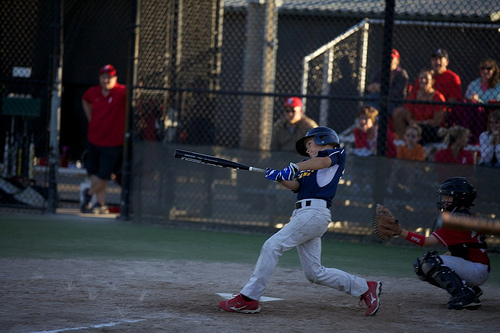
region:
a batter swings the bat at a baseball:
[173, 105, 387, 320]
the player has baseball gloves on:
[263, 160, 298, 192]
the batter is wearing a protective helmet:
[292, 123, 344, 159]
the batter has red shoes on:
[221, 277, 386, 324]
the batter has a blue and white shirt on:
[235, 148, 369, 208]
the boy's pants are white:
[246, 198, 369, 301]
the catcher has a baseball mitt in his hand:
[368, 178, 494, 311]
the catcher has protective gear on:
[413, 178, 493, 313]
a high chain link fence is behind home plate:
[133, 25, 498, 242]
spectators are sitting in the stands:
[278, 33, 497, 227]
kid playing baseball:
[170, 118, 386, 311]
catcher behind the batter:
[356, 145, 496, 310]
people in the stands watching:
[246, 15, 497, 165]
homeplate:
[211, 275, 283, 311]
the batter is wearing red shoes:
[206, 273, 387, 314]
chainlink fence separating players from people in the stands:
[135, 3, 498, 229]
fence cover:
[118, 127, 494, 237]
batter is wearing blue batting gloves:
[265, 150, 301, 185]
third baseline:
[1, 301, 191, 326]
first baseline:
[3, 262, 179, 287]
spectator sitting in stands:
[353, 100, 383, 156]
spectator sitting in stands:
[276, 93, 322, 154]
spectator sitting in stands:
[395, 123, 427, 161]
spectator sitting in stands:
[436, 126, 476, 167]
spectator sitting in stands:
[479, 113, 499, 162]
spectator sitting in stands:
[367, 48, 407, 110]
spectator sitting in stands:
[392, 69, 447, 131]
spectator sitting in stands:
[424, 44, 461, 102]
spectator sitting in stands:
[463, 57, 498, 107]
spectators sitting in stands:
[268, 44, 495, 164]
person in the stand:
[402, 128, 427, 158]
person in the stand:
[355, 106, 380, 151]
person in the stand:
[280, 98, 313, 148]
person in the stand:
[438, 127, 470, 167]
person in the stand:
[416, 70, 448, 116]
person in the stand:
[468, 55, 497, 100]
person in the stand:
[427, 49, 456, 89]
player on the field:
[245, 110, 386, 312]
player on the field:
[383, 177, 493, 305]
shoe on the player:
[209, 291, 267, 316]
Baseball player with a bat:
[147, 94, 383, 319]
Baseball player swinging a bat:
[175, 102, 385, 324]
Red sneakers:
[210, 269, 406, 319]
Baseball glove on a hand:
[357, 173, 411, 248]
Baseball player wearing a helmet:
[290, 118, 345, 161]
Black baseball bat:
[166, 139, 264, 183]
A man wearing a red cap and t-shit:
[72, 57, 134, 145]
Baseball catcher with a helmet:
[364, 147, 495, 310]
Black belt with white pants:
[270, 191, 340, 216]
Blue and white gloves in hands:
[262, 159, 301, 188]